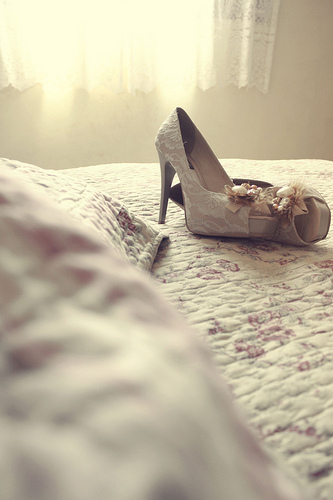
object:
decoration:
[223, 180, 313, 223]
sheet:
[39, 158, 333, 499]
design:
[215, 257, 241, 274]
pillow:
[1, 138, 174, 279]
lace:
[182, 181, 251, 241]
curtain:
[0, 0, 278, 115]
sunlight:
[7, 14, 267, 147]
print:
[215, 259, 244, 273]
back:
[152, 106, 178, 226]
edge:
[0, 158, 333, 169]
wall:
[6, 2, 331, 166]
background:
[0, 0, 331, 180]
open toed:
[288, 190, 330, 245]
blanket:
[0, 151, 331, 497]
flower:
[223, 177, 265, 204]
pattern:
[232, 243, 332, 411]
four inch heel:
[157, 152, 175, 225]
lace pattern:
[226, 184, 261, 235]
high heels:
[148, 100, 332, 252]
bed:
[2, 151, 332, 500]